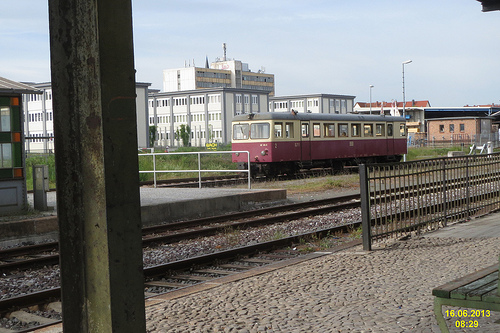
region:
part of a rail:
[399, 161, 407, 169]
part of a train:
[289, 118, 299, 130]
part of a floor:
[336, 273, 340, 283]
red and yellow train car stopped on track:
[217, 99, 421, 182]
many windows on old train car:
[225, 109, 415, 176]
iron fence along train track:
[342, 152, 495, 258]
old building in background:
[156, 50, 286, 161]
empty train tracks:
[0, 181, 390, 298]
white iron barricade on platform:
[136, 134, 253, 202]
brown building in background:
[417, 107, 496, 157]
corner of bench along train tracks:
[412, 250, 497, 330]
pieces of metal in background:
[440, 132, 495, 188]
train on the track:
[221, 87, 420, 184]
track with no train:
[194, 217, 274, 224]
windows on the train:
[237, 128, 267, 141]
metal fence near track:
[363, 158, 463, 225]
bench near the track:
[438, 267, 498, 322]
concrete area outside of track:
[375, 225, 447, 314]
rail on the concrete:
[156, 148, 255, 185]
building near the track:
[159, 79, 277, 146]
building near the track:
[278, 91, 357, 131]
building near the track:
[33, 76, 157, 138]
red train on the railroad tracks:
[223, 108, 416, 164]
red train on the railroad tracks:
[214, 110, 417, 162]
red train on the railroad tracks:
[224, 105, 419, 174]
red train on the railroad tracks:
[221, 107, 413, 182]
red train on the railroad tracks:
[221, 95, 416, 179]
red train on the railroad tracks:
[221, 101, 412, 186]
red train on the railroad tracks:
[212, 96, 414, 178]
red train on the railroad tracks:
[225, 100, 415, 177]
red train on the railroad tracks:
[219, 100, 416, 185]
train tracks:
[205, 215, 235, 230]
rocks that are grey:
[285, 274, 360, 323]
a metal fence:
[373, 173, 428, 220]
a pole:
[64, 95, 132, 331]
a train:
[237, 117, 407, 155]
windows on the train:
[277, 122, 322, 139]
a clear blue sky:
[315, 30, 391, 55]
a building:
[175, 96, 230, 136]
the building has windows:
[162, 91, 209, 107]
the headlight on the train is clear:
[258, 149, 268, 156]